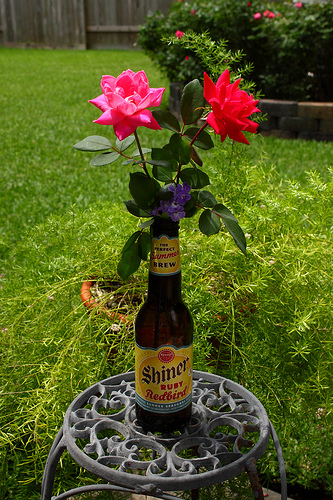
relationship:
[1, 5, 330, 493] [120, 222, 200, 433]
image has a beer bottle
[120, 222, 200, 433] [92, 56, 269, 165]
bottle full of flowers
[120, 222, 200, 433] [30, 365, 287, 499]
bottle on a stool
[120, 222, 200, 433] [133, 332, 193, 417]
beer bottle has label